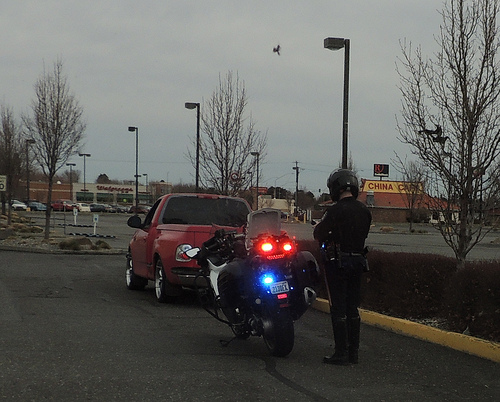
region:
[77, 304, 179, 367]
the street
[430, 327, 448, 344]
a yellow curb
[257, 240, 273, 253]
red light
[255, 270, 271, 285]
blue light on the motorcycle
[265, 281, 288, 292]
license plate on the motorcycle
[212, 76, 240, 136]
the tree branches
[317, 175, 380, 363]
a police officer standing wearing black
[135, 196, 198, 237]
a truck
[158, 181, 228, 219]
the truck is red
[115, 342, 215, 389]
the street is black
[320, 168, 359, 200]
man wearing a black helmet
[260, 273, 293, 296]
license plate on a motorcycle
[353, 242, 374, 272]
gun in a holster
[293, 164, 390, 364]
Cop writing a ticket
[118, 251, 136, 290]
Chrome rims on a truck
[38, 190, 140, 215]
car parked in the parking lot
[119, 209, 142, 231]
mirror on the pickup truck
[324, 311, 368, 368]
Cop wearing black boots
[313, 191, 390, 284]
Cop wearing a black shirt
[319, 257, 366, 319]
cop wearing black pants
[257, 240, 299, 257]
red lights on back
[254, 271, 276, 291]
blue light on back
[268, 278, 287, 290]
white licence plate on vehicle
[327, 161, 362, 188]
black motorcycle helmet on head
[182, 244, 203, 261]
side view mirror on bike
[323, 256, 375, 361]
black pants on man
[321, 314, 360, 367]
black boots on man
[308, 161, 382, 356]
cop dressed in uniform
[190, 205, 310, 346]
motorcycle of a cop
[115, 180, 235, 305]
red pic up truck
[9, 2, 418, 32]
a gray sky in the background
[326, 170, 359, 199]
the helmet of the police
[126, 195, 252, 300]
this is a red pick up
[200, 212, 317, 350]
the police motorcycle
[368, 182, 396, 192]
the word CHINA in the distance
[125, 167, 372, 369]
the police is giving a ticket to the driver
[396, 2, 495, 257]
a dry tree to the right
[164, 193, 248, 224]
the rear windshield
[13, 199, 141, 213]
several cars in the distance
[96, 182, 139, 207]
looks like walgreens pharmacy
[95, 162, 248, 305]
a red pick up truck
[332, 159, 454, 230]
this is a Chinese restaurant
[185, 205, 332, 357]
this is a police motorcycle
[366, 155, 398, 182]
this is a sign for Radioshack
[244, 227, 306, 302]
red and blue lights on the motorcycle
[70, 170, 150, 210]
this is a drugstore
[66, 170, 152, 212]
this is a Walgreens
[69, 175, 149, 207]
a Walgreens drug store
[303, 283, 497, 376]
the curb is yellow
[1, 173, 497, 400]
this is a parking lot